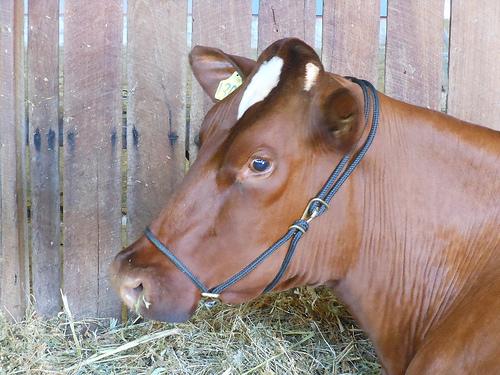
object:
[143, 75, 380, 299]
rope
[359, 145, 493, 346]
wrinkles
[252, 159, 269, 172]
eye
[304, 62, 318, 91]
spot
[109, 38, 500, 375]
cow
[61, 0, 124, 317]
timber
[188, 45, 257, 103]
cows ear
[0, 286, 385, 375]
hay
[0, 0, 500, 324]
fence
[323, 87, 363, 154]
ear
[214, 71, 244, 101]
ear tag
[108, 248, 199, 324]
muzzle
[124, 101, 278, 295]
face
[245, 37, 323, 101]
forehead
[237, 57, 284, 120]
pattern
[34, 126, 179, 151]
stains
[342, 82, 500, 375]
neck